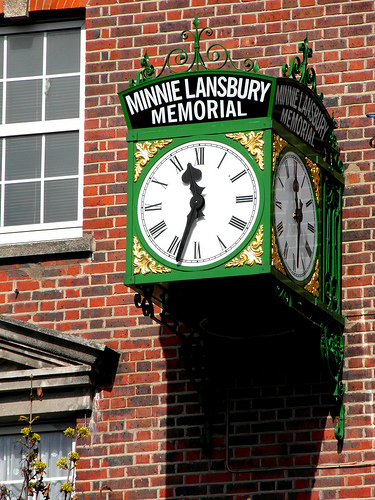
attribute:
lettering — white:
[117, 72, 276, 127]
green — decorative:
[118, 15, 276, 287]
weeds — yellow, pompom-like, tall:
[0, 415, 90, 498]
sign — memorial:
[116, 14, 274, 124]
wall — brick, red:
[88, 3, 132, 84]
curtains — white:
[1, 434, 73, 500]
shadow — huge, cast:
[155, 309, 314, 499]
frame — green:
[112, 8, 351, 452]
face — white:
[134, 138, 262, 270]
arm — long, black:
[176, 207, 200, 266]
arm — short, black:
[179, 161, 206, 193]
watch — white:
[272, 121, 319, 295]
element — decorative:
[21, 382, 89, 493]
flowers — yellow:
[62, 433, 75, 492]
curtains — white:
[7, 436, 73, 498]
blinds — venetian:
[3, 23, 78, 246]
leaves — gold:
[234, 125, 263, 164]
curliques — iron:
[130, 20, 260, 73]